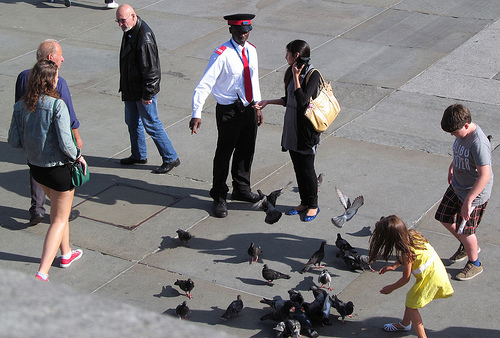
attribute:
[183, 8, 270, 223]
man — pointing down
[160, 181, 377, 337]
birds — grouped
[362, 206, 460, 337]
girl — bending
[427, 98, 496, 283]
shorts — brown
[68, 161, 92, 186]
clutch — green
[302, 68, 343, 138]
pocket book — brown, gold, large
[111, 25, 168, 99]
jacket — leather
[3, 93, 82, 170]
jacket — blue jean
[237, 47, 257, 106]
tie — red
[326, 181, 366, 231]
bird — flying away, flying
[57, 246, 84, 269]
shoe — red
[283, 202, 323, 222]
sandals — blue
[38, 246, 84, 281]
shoes — pink, white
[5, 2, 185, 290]
people — walking